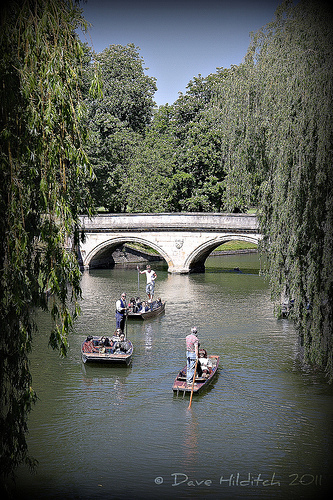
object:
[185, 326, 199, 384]
man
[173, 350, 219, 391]
boat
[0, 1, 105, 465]
trees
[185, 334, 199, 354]
shirt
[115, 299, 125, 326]
shirt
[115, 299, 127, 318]
vest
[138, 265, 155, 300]
man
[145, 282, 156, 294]
shorts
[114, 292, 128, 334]
people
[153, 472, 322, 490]
sign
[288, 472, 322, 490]
year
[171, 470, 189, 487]
letters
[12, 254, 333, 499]
water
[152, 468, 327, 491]
copyright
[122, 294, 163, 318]
boat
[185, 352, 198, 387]
jeans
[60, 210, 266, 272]
bridge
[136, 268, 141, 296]
pole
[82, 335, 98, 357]
people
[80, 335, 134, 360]
boat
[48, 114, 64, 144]
leaves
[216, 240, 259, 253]
lawn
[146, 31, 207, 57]
blue